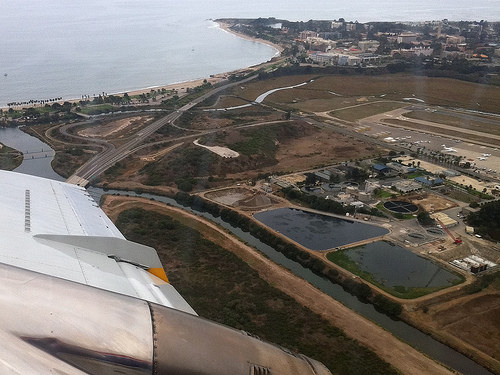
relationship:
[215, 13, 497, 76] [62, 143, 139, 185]
city contains a highway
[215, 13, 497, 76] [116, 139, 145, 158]
city contains a highway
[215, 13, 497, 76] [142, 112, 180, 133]
city contains a highway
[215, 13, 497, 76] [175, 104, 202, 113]
city contains a highway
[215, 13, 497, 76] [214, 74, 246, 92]
city contains a highway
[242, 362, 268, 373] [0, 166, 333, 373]
vent on airplane wing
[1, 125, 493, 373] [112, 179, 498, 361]
creek down city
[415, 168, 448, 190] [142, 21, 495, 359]
building on ground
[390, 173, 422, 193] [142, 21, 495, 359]
building on ground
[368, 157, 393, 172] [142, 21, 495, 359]
building on ground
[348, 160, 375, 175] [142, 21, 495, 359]
building on ground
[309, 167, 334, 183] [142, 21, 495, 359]
building on ground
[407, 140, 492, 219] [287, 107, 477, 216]
trees on ground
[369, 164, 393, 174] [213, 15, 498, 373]
building on ground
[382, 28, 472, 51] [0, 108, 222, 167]
buildings on ground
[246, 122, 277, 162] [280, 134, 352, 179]
trees on ground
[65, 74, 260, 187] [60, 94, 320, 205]
highway on ground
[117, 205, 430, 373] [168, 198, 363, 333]
trees by water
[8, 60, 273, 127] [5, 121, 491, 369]
beach has water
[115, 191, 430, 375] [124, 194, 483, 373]
trees along canal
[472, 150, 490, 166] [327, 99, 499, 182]
airplane on ground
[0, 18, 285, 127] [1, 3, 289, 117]
beach along edge of water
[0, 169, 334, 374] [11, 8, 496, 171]
airplane flying low to ground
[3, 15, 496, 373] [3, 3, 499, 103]
land jutting into water